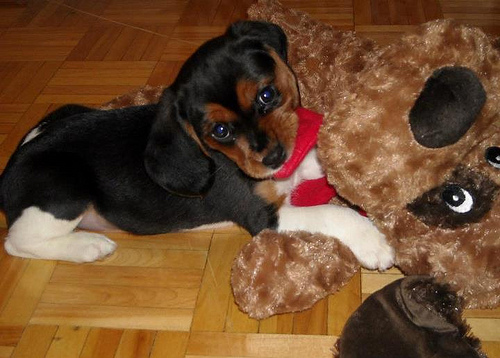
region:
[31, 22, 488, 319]
A real puppy and a toy puppy.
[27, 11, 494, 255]
A real puppy plays with a stuffed puppy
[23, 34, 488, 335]
The two puppies are watching the camera.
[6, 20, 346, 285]
The real puppy is black and brown.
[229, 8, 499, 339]
The stuffed animal puppy is light and dark brown.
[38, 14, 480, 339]
The real puppy plays with fake puppy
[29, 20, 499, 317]
A real puppy and a fake puppy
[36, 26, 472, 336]
The real puppy has white feet.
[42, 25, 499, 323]
The fake puppy has light brown feet.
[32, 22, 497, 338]
Two puppies playing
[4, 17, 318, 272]
a puppy cuddled with a stuffed animal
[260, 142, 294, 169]
a black puppy nose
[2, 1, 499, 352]
a light brown wood floor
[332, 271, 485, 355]
a dark brown ear of a stuffed dog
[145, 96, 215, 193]
a black ear on a puppy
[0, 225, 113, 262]
the white hind foot of a puppy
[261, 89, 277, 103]
the round black eye of a puppy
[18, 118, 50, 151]
a white spot on a puppy's back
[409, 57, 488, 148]
the nose on a stuffed dog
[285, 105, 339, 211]
a red bow on a stuffed dog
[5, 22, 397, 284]
black brown and white puppy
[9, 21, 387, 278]
puppy laying on floor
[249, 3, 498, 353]
brown plush stuffed dog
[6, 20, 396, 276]
puppy playing with stuffed dog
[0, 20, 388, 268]
dog laying on stuffed toy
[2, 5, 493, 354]
brown hardwood floor tiles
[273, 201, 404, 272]
white fur puppy paw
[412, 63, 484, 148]
fabric covered nose on toy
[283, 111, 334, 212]
red fabric under dog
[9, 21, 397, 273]
dog laying on wood floor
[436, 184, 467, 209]
pupil of toy dog's eye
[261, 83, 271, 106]
shine on pupil of dog's eye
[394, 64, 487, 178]
nose of the toy dog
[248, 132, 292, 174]
nose of the puppy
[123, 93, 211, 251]
right ear of the puppy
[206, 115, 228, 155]
eye of the puppy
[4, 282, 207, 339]
wood square on the floor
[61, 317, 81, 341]
knot in the woog floor tile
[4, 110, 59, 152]
white spot on puppy's back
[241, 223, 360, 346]
toy dog's left arm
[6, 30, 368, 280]
The dog has black, brown, and white fur.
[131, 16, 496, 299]
The dog is sitting next to a big stuffed dog.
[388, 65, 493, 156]
The stuffed animal has a brown nose.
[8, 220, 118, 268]
The back leg of the dog is white.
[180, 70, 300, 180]
The dog has a brown mask on the face.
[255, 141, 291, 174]
The dog has a black nose.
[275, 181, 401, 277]
The dog has a white front leg.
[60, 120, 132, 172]
The back of the dog is covered in black fur.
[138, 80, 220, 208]
The dog has a floppy ear.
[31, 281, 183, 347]
The floor has wood boards on it.